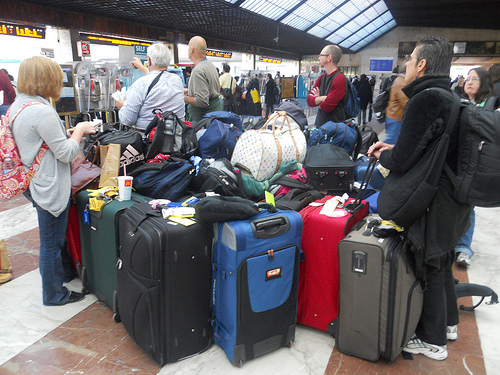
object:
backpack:
[426, 88, 500, 207]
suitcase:
[295, 194, 369, 339]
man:
[364, 37, 478, 362]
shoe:
[400, 333, 449, 363]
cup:
[116, 175, 134, 201]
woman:
[0, 55, 98, 309]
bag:
[96, 143, 123, 189]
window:
[240, 0, 256, 9]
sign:
[367, 59, 394, 73]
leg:
[35, 175, 71, 305]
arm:
[378, 91, 441, 174]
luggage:
[334, 212, 425, 363]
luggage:
[214, 201, 301, 367]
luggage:
[113, 201, 214, 368]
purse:
[230, 110, 309, 182]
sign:
[0, 21, 47, 39]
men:
[113, 41, 186, 135]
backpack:
[0, 100, 51, 203]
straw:
[123, 162, 128, 176]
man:
[181, 34, 223, 123]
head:
[185, 34, 206, 63]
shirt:
[305, 69, 353, 128]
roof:
[0, 0, 500, 61]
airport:
[0, 0, 499, 375]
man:
[306, 44, 351, 131]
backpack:
[343, 73, 362, 119]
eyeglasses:
[318, 53, 328, 58]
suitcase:
[79, 187, 156, 323]